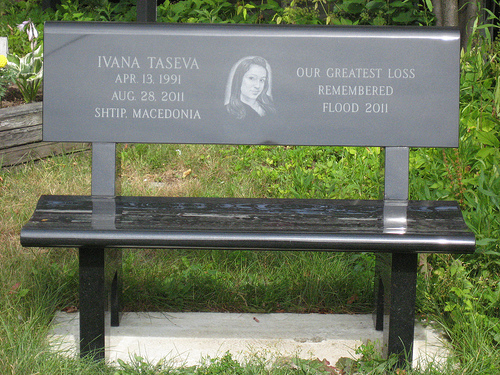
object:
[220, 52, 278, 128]
girl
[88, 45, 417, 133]
remembrance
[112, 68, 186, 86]
birth date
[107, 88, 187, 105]
death date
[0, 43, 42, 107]
flowers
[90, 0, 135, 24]
bushes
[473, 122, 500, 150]
leaves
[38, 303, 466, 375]
floor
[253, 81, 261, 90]
nose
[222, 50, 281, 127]
lady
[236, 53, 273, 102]
head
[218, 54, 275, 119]
woman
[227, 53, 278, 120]
hair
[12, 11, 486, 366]
bench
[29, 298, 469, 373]
cement slab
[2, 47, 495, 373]
grass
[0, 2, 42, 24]
plants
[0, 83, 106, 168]
planter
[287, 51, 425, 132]
text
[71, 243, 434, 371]
supports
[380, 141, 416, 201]
back supports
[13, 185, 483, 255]
seat